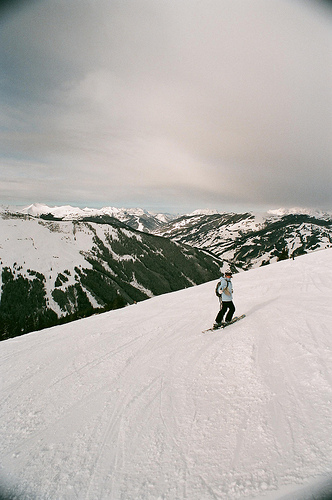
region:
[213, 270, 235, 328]
Person standing upright in the snow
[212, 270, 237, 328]
Person wearing a backpack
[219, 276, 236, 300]
Light blue jacket with a hood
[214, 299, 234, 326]
Black pair of pants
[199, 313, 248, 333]
Skis on the ice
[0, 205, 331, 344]
Seriesof mountain ranges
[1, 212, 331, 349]
Sparce snow cover on the mountains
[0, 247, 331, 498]
Smooth sheet of snow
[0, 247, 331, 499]
Snow sheet on a gentle slope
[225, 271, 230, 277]
Dark shaded pair of goggles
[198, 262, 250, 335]
a skier on a slope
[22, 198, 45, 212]
a snow capped mountaintop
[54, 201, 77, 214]
a snow capped mountaintop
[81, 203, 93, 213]
a snow capped mountaintop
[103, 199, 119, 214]
a snow capped mountaintop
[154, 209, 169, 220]
a snow capped mountaintop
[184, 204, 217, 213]
a snow capped mountaintop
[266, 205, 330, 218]
a snow capped mountaintop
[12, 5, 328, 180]
an overcast sky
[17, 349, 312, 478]
thick fluffy white snow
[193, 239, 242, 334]
A person on the slope.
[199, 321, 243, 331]
Person is wearing skis.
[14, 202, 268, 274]
The mountains is covered with snow.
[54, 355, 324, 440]
Ski tracks on the ground.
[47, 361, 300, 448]
The ground is covered with snow.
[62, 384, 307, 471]
The snow is white.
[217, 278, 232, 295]
The person is carrying a backpack.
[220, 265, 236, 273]
The person is wearing a helmet.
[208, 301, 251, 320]
The pants are black.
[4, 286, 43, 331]
Trees on the mountain.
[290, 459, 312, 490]
part of the snow on the ground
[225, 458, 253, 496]
part of the snow on the ground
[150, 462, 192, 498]
part of the snow on the ground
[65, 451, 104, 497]
part of the snow on the ground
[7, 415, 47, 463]
part of the snow on the ground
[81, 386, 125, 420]
part of the snow on the ground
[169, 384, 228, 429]
part of the snow on the ground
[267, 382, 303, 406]
part of the snow on the ground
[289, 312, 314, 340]
part of the snow on the ground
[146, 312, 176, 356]
part of the snow on the ground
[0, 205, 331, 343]
green mountains over with snow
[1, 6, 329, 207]
light blue cloudy sky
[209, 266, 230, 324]
snowboarder wearing light blue jacket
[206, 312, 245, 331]
green snowboard in the snow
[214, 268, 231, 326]
snowboarder wearing black pants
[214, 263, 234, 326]
snowboarder rolling on a mountain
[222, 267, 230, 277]
white balaclava of snowboarder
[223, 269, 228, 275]
black glasses of snowboarder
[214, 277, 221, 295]
black bagpack of snowbaorder